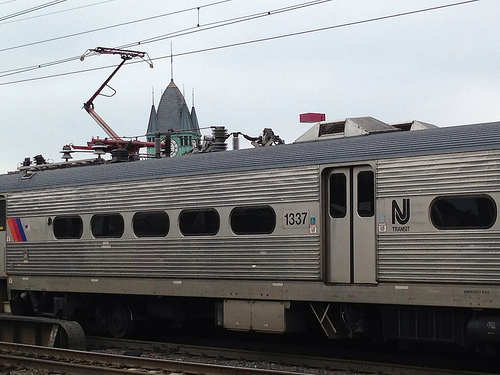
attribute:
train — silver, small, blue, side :
[0, 116, 499, 351]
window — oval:
[226, 199, 280, 238]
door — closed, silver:
[320, 161, 380, 286]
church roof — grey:
[141, 44, 204, 147]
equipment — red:
[70, 41, 159, 139]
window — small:
[44, 204, 87, 240]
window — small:
[86, 206, 127, 242]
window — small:
[124, 204, 174, 242]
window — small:
[175, 199, 222, 239]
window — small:
[224, 194, 280, 239]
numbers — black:
[281, 208, 311, 226]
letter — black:
[388, 223, 413, 235]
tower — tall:
[142, 35, 203, 153]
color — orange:
[5, 216, 18, 243]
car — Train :
[4, 140, 476, 345]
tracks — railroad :
[74, 325, 417, 368]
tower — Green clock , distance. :
[115, 30, 222, 170]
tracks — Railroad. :
[27, 318, 482, 373]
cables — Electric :
[9, 4, 355, 83]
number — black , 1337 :
[276, 209, 308, 235]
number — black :
[285, 203, 320, 235]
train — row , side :
[54, 166, 464, 320]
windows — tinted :
[435, 202, 482, 233]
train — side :
[11, 153, 470, 353]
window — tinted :
[234, 196, 277, 239]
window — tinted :
[232, 208, 277, 227]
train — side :
[4, 96, 484, 336]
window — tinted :
[182, 213, 219, 234]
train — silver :
[40, 109, 481, 365]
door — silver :
[316, 150, 387, 327]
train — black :
[53, 120, 452, 353]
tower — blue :
[129, 56, 216, 186]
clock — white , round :
[144, 111, 196, 191]